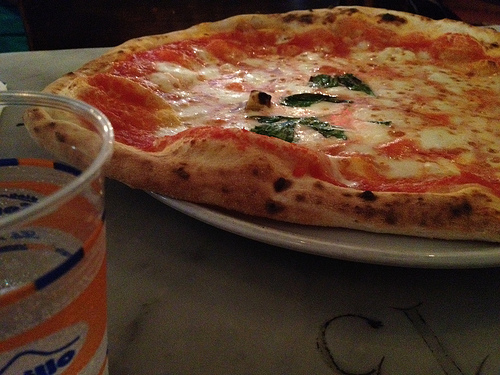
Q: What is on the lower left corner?
A: Blue, orange, and clear cup.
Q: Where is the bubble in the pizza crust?
A: Lower left section of pizza.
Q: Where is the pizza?
A: On a metal pan.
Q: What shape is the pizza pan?
A: Circle.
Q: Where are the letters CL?
A: On the table.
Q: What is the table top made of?
A: Marble.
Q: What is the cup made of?
A: Plastic.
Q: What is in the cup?
A: Clear, bubbly soda.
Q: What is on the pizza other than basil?
A: Cheese and marinara sauce.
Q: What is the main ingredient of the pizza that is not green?
A: Cheese.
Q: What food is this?
A: Pizza.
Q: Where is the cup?
A: On the table.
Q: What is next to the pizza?
A: Cup of water.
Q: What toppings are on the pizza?
A: Cheese and spinach.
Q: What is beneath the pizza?
A: A plate.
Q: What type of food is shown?
A: Pizza.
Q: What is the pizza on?
A: Plate.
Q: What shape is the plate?
A: Round.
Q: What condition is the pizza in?
A: Cooked and uncut.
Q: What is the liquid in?
A: Cup.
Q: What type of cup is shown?
A: Plastic.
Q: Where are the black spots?
A: Pizza crust.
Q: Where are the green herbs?
A: Center of the pizza.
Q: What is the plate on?
A: Table.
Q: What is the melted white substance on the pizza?
A: Cheese.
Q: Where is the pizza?
A: On the white plate.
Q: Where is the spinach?
A: On the pizza.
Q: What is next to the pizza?
A: A plastic cup.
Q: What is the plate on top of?
A: The table.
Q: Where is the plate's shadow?
A: On the table.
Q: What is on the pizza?
A: Cheese, sauce and spinach.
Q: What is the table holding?
A: A plate with a pizza and a plastic cup.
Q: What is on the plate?
A: Pizza.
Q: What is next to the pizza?
A: A cup.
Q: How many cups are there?
A: One.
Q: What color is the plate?
A: White.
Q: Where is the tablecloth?
A: Under the plate.